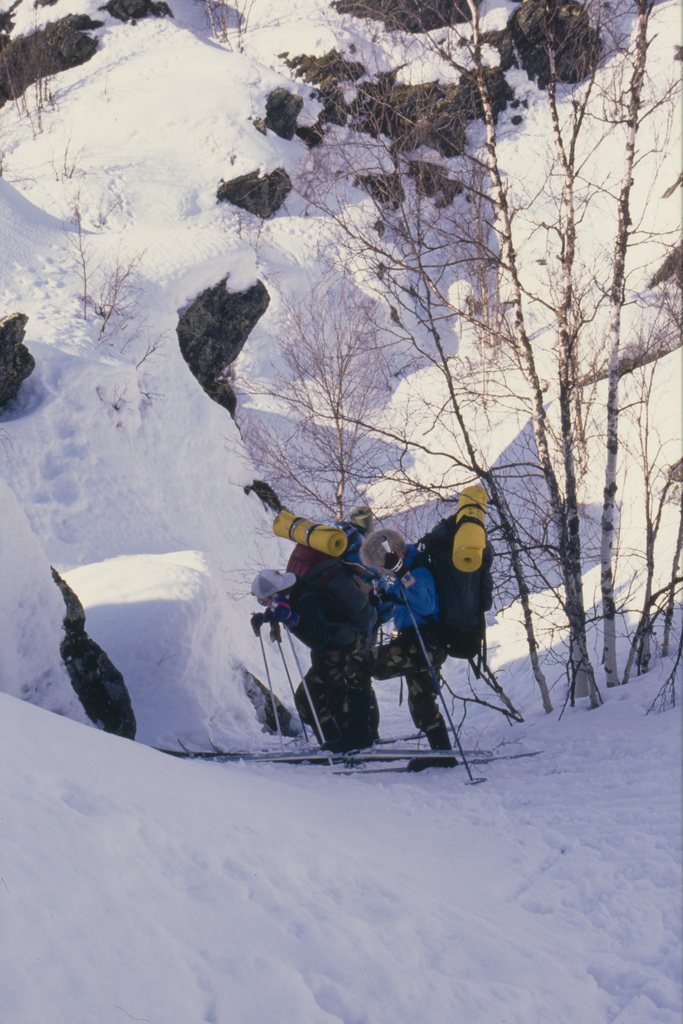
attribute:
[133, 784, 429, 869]
snow — white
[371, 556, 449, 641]
jacket — blue , teal 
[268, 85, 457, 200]
rock — covered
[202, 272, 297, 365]
rock — covered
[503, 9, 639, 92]
rock — covered